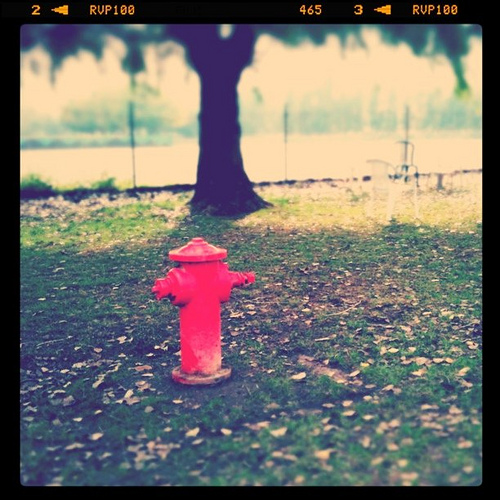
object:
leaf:
[291, 373, 306, 383]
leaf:
[271, 426, 286, 440]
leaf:
[218, 426, 235, 437]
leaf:
[185, 424, 200, 438]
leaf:
[88, 431, 99, 443]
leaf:
[315, 446, 332, 463]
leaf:
[412, 369, 426, 376]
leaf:
[457, 435, 472, 456]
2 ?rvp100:
[27, 0, 139, 18]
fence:
[240, 91, 466, 204]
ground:
[240, 218, 484, 463]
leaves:
[116, 379, 155, 422]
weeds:
[23, 174, 127, 201]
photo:
[23, 24, 483, 479]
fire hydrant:
[142, 232, 260, 391]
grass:
[20, 171, 482, 484]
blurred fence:
[19, 100, 486, 194]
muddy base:
[169, 360, 234, 387]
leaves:
[252, 207, 464, 420]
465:
[299, 4, 322, 15]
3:
[354, 3, 362, 14]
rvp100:
[412, 5, 457, 15]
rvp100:
[89, 5, 134, 15]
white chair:
[350, 150, 409, 210]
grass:
[250, 172, 498, 253]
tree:
[22, 24, 486, 221]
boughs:
[238, 214, 412, 321]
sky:
[19, 25, 483, 145]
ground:
[21, 170, 481, 486]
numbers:
[295, 1, 326, 20]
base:
[171, 362, 233, 387]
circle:
[163, 365, 235, 399]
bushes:
[20, 74, 481, 149]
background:
[24, 30, 471, 216]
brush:
[51, 74, 461, 150]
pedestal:
[167, 364, 246, 387]